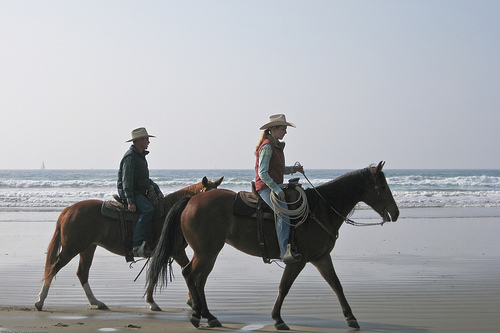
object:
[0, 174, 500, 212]
foam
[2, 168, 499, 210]
water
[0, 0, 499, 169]
clouds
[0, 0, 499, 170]
sky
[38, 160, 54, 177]
boat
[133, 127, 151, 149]
head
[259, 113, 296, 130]
hat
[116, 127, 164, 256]
man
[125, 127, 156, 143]
hat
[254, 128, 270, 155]
blonde ponytail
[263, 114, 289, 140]
head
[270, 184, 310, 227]
lasso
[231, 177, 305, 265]
saddle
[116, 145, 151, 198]
green vest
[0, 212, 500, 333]
beach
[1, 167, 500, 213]
ocean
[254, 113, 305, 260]
woman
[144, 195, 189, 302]
tail hair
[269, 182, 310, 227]
lap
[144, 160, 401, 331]
horses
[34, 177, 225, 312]
horses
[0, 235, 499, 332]
sand